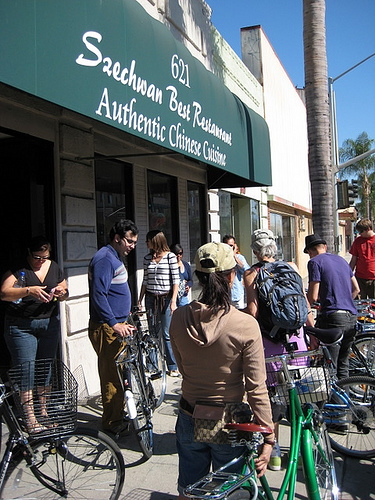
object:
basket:
[5, 357, 77, 439]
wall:
[0, 107, 95, 410]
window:
[269, 207, 297, 270]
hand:
[0, 416, 123, 500]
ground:
[0, 306, 375, 500]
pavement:
[3, 252, 375, 498]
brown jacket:
[168, 298, 275, 436]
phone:
[43, 286, 51, 298]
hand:
[29, 285, 50, 303]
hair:
[191, 254, 238, 318]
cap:
[194, 241, 237, 272]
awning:
[0, 0, 273, 189]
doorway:
[0, 127, 63, 436]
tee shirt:
[11, 258, 66, 320]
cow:
[142, 250, 179, 296]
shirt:
[87, 241, 132, 321]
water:
[9, 270, 26, 305]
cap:
[250, 228, 274, 241]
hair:
[109, 218, 139, 242]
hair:
[26, 229, 52, 269]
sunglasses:
[27, 247, 51, 261]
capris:
[3, 313, 61, 391]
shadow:
[163, 0, 227, 82]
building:
[0, 0, 356, 401]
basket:
[263, 346, 332, 408]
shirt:
[348, 237, 375, 281]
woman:
[136, 230, 179, 378]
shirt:
[142, 250, 179, 296]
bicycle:
[257, 323, 374, 461]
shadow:
[49, 408, 179, 457]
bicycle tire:
[0, 428, 126, 500]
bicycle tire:
[323, 377, 375, 460]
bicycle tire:
[122, 368, 155, 460]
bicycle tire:
[340, 324, 375, 378]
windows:
[145, 167, 181, 251]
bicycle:
[182, 343, 339, 500]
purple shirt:
[307, 251, 358, 316]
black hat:
[303, 232, 327, 253]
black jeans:
[312, 309, 358, 405]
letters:
[74, 29, 231, 170]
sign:
[0, 0, 273, 189]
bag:
[191, 402, 234, 447]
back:
[167, 306, 276, 443]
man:
[346, 215, 375, 296]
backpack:
[253, 259, 308, 343]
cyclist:
[0, 238, 70, 433]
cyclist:
[88, 218, 140, 437]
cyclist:
[167, 241, 275, 498]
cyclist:
[245, 228, 315, 473]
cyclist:
[303, 235, 360, 436]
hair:
[250, 238, 277, 260]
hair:
[146, 229, 172, 260]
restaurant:
[0, 0, 273, 191]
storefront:
[0, 90, 211, 422]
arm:
[2, 274, 31, 310]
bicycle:
[0, 359, 127, 500]